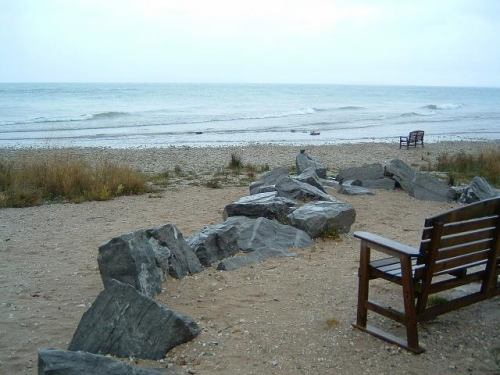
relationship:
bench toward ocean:
[353, 196, 498, 357] [1, 83, 497, 151]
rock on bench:
[70, 279, 202, 359] [0, 140, 499, 374]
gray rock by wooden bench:
[105, 232, 196, 277] [344, 212, 469, 332]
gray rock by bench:
[105, 232, 196, 277] [0, 140, 499, 374]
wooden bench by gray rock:
[344, 212, 469, 332] [105, 232, 196, 277]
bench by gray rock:
[0, 140, 499, 374] [105, 232, 196, 277]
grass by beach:
[3, 144, 134, 223] [3, 181, 223, 239]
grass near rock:
[3, 144, 134, 223] [218, 189, 351, 239]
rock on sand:
[265, 353, 276, 363] [0, 139, 496, 373]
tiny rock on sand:
[215, 286, 227, 293] [262, 286, 333, 341]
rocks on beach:
[30, 155, 483, 373] [8, 212, 353, 363]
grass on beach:
[451, 147, 495, 176] [13, 145, 351, 357]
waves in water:
[7, 99, 469, 127] [9, 88, 455, 142]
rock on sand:
[224, 190, 294, 221] [0, 139, 496, 373]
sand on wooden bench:
[203, 275, 318, 355] [349, 195, 499, 354]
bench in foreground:
[353, 196, 498, 357] [4, 146, 493, 372]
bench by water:
[0, 140, 499, 374] [213, 87, 322, 139]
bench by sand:
[353, 196, 498, 357] [0, 139, 496, 373]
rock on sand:
[65, 270, 207, 361] [154, 286, 255, 333]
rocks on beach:
[30, 155, 483, 373] [2, 140, 499, 370]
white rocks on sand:
[209, 312, 281, 360] [206, 273, 346, 373]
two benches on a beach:
[349, 120, 498, 360] [15, 145, 484, 355]